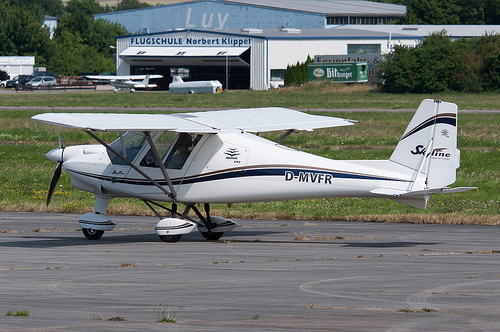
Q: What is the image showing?
A: It is showing a pavement.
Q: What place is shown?
A: It is a pavement.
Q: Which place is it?
A: It is a pavement.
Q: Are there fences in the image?
A: No, there are no fences.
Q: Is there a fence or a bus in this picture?
A: No, there are no fences or buses.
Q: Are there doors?
A: Yes, there is a door.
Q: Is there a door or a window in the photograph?
A: Yes, there is a door.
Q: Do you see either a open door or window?
A: Yes, there is an open door.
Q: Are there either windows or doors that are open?
A: Yes, the door is open.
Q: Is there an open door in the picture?
A: Yes, there is an open door.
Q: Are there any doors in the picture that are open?
A: Yes, there is a door that is open.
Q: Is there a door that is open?
A: Yes, there is a door that is open.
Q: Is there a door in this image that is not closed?
A: Yes, there is a open door.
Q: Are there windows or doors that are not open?
A: No, there is a door but it is open.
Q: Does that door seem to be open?
A: Yes, the door is open.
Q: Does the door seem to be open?
A: Yes, the door is open.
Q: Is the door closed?
A: No, the door is open.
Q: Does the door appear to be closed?
A: No, the door is open.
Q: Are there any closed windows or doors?
A: No, there is a door but it is open.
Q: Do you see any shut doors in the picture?
A: No, there is a door but it is open.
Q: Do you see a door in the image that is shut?
A: No, there is a door but it is open.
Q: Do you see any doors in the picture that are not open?
A: No, there is a door but it is open.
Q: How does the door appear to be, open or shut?
A: The door is open.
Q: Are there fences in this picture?
A: No, there are no fences.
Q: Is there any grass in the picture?
A: Yes, there is grass.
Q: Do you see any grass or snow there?
A: Yes, there is grass.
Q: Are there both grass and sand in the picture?
A: No, there is grass but no sand.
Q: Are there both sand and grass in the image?
A: No, there is grass but no sand.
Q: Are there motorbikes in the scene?
A: No, there are no motorbikes.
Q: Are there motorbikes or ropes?
A: No, there are no motorbikes or ropes.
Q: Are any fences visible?
A: No, there are no fences.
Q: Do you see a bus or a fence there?
A: No, there are no fences or buses.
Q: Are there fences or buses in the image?
A: No, there are no fences or buses.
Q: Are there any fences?
A: No, there are no fences.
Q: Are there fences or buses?
A: No, there are no fences or buses.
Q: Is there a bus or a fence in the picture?
A: No, there are no fences or buses.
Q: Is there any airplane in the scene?
A: Yes, there is an airplane.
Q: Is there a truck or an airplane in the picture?
A: Yes, there is an airplane.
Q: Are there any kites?
A: No, there are no kites.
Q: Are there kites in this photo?
A: No, there are no kites.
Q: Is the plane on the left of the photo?
A: Yes, the plane is on the left of the image.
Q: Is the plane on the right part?
A: No, the plane is on the left of the image.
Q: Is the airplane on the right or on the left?
A: The airplane is on the left of the image.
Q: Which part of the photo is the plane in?
A: The plane is on the left of the image.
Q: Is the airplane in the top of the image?
A: Yes, the airplane is in the top of the image.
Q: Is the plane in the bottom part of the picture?
A: No, the plane is in the top of the image.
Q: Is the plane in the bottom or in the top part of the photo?
A: The plane is in the top of the image.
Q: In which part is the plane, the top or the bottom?
A: The plane is in the top of the image.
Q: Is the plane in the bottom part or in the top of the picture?
A: The plane is in the top of the image.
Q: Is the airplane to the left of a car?
A: No, the airplane is to the right of a car.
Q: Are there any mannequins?
A: No, there are no mannequins.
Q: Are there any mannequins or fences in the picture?
A: No, there are no mannequins or fences.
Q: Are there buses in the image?
A: No, there are no buses.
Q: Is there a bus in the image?
A: No, there are no buses.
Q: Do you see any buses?
A: No, there are no buses.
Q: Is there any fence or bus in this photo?
A: No, there are no buses or fences.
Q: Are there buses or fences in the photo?
A: No, there are no buses or fences.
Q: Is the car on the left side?
A: Yes, the car is on the left of the image.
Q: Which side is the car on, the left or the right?
A: The car is on the left of the image.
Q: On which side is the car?
A: The car is on the left of the image.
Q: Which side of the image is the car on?
A: The car is on the left of the image.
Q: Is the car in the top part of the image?
A: Yes, the car is in the top of the image.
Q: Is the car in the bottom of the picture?
A: No, the car is in the top of the image.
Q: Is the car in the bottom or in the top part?
A: The car is in the top of the image.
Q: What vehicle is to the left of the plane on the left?
A: The vehicle is a car.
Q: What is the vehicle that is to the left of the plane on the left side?
A: The vehicle is a car.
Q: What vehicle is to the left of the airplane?
A: The vehicle is a car.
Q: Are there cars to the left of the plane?
A: Yes, there is a car to the left of the plane.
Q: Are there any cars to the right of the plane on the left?
A: No, the car is to the left of the airplane.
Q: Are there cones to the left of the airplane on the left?
A: No, there is a car to the left of the airplane.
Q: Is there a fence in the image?
A: No, there are no fences.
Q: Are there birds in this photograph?
A: No, there are no birds.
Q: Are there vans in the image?
A: No, there are no vans.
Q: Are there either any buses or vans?
A: No, there are no vans or buses.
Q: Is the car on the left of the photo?
A: Yes, the car is on the left of the image.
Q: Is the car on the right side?
A: No, the car is on the left of the image.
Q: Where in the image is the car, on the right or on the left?
A: The car is on the left of the image.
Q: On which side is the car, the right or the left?
A: The car is on the left of the image.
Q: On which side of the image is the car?
A: The car is on the left of the image.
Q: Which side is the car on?
A: The car is on the left of the image.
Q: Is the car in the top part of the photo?
A: Yes, the car is in the top of the image.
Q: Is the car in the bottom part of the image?
A: No, the car is in the top of the image.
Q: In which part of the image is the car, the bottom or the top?
A: The car is in the top of the image.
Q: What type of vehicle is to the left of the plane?
A: The vehicle is a car.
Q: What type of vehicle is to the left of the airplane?
A: The vehicle is a car.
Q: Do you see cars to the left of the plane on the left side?
A: Yes, there is a car to the left of the airplane.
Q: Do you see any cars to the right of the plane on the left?
A: No, the car is to the left of the airplane.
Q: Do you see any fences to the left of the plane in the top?
A: No, there is a car to the left of the plane.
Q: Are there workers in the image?
A: No, there are no workers.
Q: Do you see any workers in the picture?
A: No, there are no workers.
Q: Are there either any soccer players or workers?
A: No, there are no workers or soccer players.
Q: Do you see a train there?
A: No, there are no trains.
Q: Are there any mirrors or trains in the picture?
A: No, there are no trains or mirrors.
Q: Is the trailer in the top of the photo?
A: Yes, the trailer is in the top of the image.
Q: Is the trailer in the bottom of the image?
A: No, the trailer is in the top of the image.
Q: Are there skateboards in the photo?
A: No, there are no skateboards.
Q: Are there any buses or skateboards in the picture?
A: No, there are no skateboards or buses.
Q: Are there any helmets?
A: No, there are no helmets.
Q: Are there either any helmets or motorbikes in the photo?
A: No, there are no helmets or motorbikes.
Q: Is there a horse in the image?
A: No, there are no horses.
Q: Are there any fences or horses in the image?
A: No, there are no horses or fences.